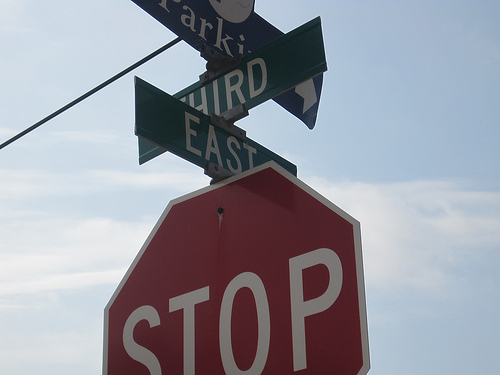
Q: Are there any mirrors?
A: No, there are no mirrors.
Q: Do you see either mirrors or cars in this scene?
A: No, there are no mirrors or cars.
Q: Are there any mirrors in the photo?
A: No, there are no mirrors.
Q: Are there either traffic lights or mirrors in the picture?
A: No, there are no mirrors or traffic lights.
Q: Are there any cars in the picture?
A: No, there are no cars.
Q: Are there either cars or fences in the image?
A: No, there are no cars or fences.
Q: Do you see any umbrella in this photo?
A: No, there are no umbrellas.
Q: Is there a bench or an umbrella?
A: No, there are no umbrellas or benches.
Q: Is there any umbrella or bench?
A: No, there are no umbrellas or benches.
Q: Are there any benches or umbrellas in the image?
A: No, there are no umbrellas or benches.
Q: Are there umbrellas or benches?
A: No, there are no umbrellas or benches.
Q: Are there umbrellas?
A: No, there are no umbrellas.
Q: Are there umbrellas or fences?
A: No, there are no umbrellas or fences.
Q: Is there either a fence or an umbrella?
A: No, there are no umbrellas or fences.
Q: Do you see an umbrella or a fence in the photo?
A: No, there are no umbrellas or fences.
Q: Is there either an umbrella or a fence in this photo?
A: No, there are no umbrellas or fences.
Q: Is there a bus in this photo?
A: No, there are no buses.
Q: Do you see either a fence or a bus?
A: No, there are no buses or fences.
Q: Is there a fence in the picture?
A: No, there are no fences.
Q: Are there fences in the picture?
A: No, there are no fences.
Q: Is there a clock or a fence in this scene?
A: No, there are no fences or clocks.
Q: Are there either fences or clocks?
A: No, there are no fences or clocks.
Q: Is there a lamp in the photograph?
A: No, there are no lamps.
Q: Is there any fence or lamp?
A: No, there are no lamps or fences.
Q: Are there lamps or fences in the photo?
A: No, there are no lamps or fences.